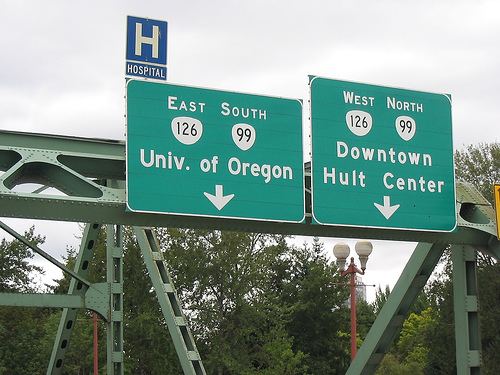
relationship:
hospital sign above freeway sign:
[123, 11, 171, 84] [124, 75, 306, 225]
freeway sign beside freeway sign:
[124, 75, 306, 225] [306, 65, 455, 234]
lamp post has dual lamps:
[325, 238, 382, 364] [331, 240, 376, 283]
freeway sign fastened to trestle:
[306, 73, 458, 233] [2, 122, 499, 375]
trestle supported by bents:
[2, 122, 499, 375] [42, 222, 499, 375]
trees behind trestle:
[2, 134, 499, 375] [2, 122, 499, 375]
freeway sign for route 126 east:
[124, 75, 306, 225] [162, 90, 208, 150]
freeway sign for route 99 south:
[124, 75, 306, 225] [218, 100, 271, 153]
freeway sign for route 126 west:
[306, 65, 455, 234] [338, 86, 379, 139]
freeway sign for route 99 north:
[306, 65, 455, 234] [384, 94, 428, 144]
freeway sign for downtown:
[306, 65, 455, 234] [330, 139, 435, 169]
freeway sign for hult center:
[306, 65, 455, 234] [317, 164, 448, 195]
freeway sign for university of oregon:
[124, 75, 306, 225] [135, 145, 295, 185]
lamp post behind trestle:
[76, 303, 106, 374] [0, 129, 500, 374]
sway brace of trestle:
[0, 216, 112, 314] [2, 122, 499, 375]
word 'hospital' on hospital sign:
[128, 63, 165, 81] [123, 11, 171, 84]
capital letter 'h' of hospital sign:
[130, 21, 167, 61] [123, 11, 171, 84]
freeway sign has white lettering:
[124, 75, 306, 225] [136, 94, 296, 214]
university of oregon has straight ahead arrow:
[135, 145, 295, 185] [197, 180, 241, 213]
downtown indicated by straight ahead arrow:
[330, 139, 435, 169] [368, 191, 407, 222]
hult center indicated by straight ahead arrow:
[317, 164, 448, 195] [368, 191, 407, 222]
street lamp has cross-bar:
[320, 241, 385, 366] [324, 280, 378, 293]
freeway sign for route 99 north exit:
[306, 65, 455, 234] [367, 92, 426, 221]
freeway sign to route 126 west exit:
[306, 65, 455, 234] [314, 85, 401, 224]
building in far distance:
[342, 271, 370, 312] [215, 237, 448, 322]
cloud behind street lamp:
[268, 233, 423, 277] [320, 241, 385, 366]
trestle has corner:
[2, 122, 499, 375] [451, 177, 498, 249]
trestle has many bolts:
[2, 122, 499, 375] [2, 143, 495, 320]